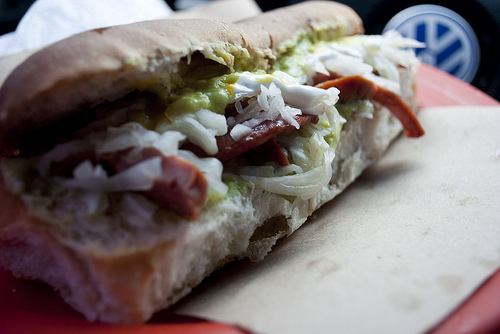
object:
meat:
[208, 103, 315, 165]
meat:
[94, 149, 205, 219]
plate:
[431, 72, 470, 107]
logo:
[380, 0, 482, 89]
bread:
[1, 0, 415, 326]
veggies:
[348, 31, 430, 57]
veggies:
[360, 73, 399, 95]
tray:
[0, 62, 498, 332]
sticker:
[316, 71, 429, 143]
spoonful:
[150, 67, 295, 152]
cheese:
[213, 67, 296, 94]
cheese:
[129, 103, 220, 149]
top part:
[0, 0, 363, 113]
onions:
[256, 84, 297, 129]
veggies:
[50, 29, 412, 221]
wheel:
[378, 0, 495, 90]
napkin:
[2, 0, 498, 330]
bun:
[6, 0, 425, 331]